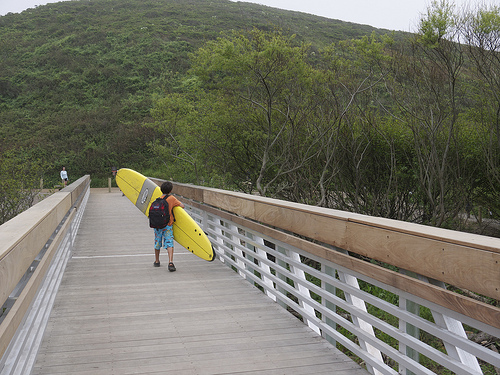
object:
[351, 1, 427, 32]
sky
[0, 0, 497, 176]
mountain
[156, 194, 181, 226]
shirt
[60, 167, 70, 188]
person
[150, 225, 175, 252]
shorts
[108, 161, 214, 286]
boy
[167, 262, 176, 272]
sandles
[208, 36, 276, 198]
green trees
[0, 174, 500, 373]
wooden bridge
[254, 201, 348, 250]
board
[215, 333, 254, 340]
boards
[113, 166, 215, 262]
surfboard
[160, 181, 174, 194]
hair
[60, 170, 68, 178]
shirt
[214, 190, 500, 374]
railing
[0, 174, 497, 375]
bridge